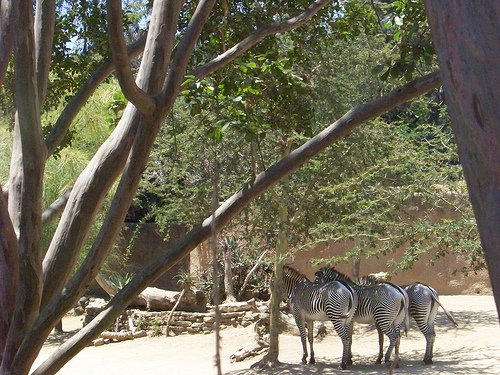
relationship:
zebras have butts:
[285, 257, 451, 346] [327, 283, 361, 326]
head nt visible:
[273, 269, 286, 295] [254, 275, 323, 313]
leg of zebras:
[330, 321, 364, 347] [285, 257, 451, 346]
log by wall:
[144, 285, 219, 314] [117, 307, 252, 349]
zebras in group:
[285, 257, 451, 346] [279, 241, 430, 348]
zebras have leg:
[285, 257, 451, 346] [334, 291, 350, 364]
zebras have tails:
[285, 257, 451, 346] [438, 306, 468, 337]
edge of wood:
[186, 298, 215, 313] [155, 236, 255, 323]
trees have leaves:
[212, 60, 357, 282] [260, 76, 277, 93]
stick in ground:
[210, 213, 230, 363] [140, 343, 272, 362]